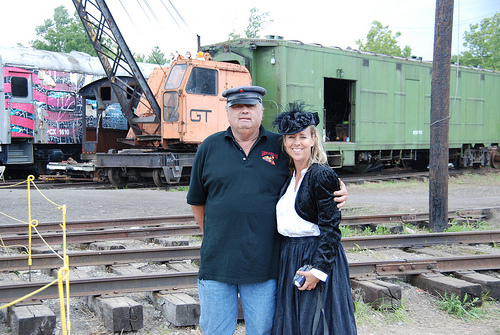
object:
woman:
[269, 100, 361, 331]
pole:
[431, 1, 451, 230]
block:
[410, 272, 482, 307]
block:
[347, 278, 390, 312]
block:
[158, 292, 202, 327]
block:
[10, 306, 37, 334]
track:
[0, 225, 500, 304]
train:
[121, 36, 500, 151]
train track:
[342, 164, 498, 183]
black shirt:
[187, 123, 293, 283]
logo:
[261, 150, 278, 166]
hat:
[268, 100, 320, 136]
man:
[187, 85, 350, 282]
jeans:
[197, 275, 278, 335]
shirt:
[268, 166, 324, 236]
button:
[114, 290, 120, 294]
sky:
[0, 0, 500, 74]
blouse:
[275, 167, 321, 238]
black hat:
[222, 85, 268, 107]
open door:
[318, 72, 359, 148]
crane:
[74, 0, 172, 143]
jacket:
[269, 162, 345, 283]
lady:
[267, 101, 358, 334]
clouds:
[0, 0, 500, 61]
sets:
[9, 210, 187, 294]